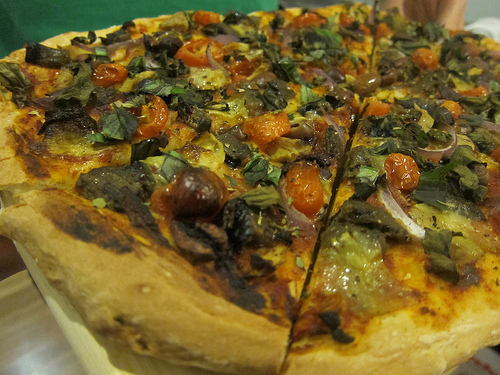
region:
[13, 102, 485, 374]
a pizza on a tray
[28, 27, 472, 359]
this pizza has vegetables on it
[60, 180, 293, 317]
this part of the pizza has been burnt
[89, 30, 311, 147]
red tomatoes are on the pizza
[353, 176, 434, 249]
meat is on the pizza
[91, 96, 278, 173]
green vegetables are on the pizza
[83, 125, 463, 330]
hte pizza has yellow sauce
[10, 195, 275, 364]
the crust on the pizza is brown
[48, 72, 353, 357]
this part of the pizza has been cut into a slice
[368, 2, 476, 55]
some person's hand is about to take a slice of the pizza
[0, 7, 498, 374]
a pizza covered in veggies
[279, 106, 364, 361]
a cut through a pizza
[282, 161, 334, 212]
a tomato on pizza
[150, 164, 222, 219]
a tomato on pizza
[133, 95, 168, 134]
a tomato on pizza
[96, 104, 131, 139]
a piece of kale on pizza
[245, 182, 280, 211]
a piece of kale on pizza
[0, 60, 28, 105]
a piece of kale on pizza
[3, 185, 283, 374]
crust of a pizza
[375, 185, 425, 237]
onion on pizza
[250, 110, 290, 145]
Yellow peppers on pizza top.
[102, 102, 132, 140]
Green veggie on pizza top.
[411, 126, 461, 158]
Red onions on pizza top.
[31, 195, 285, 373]
Pizza crust on edge of plate.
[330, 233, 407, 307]
Chessey goop on pizza top.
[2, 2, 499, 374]
Vegetable pizza on table top.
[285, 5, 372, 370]
Pizza sliced down the middle.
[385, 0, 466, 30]
Person's hand on pizza.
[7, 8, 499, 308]
Multiple veggie toppings on pizza.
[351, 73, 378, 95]
Green olive on pizza toppings.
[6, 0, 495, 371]
large round pizza with vegetables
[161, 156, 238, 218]
round whole brown mushroom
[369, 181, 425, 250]
slice of mushroom on pizza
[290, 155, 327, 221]
red small swet tomato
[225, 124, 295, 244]
sense green spinach on pizza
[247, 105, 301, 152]
piece of cooked cherry tomato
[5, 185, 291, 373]
golden crispy crust of pizza slice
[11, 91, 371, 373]
triangular piece of vegetarian pizza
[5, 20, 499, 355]
melted yellow cheese on pizza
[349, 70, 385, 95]
shiny green olive in center of pizza